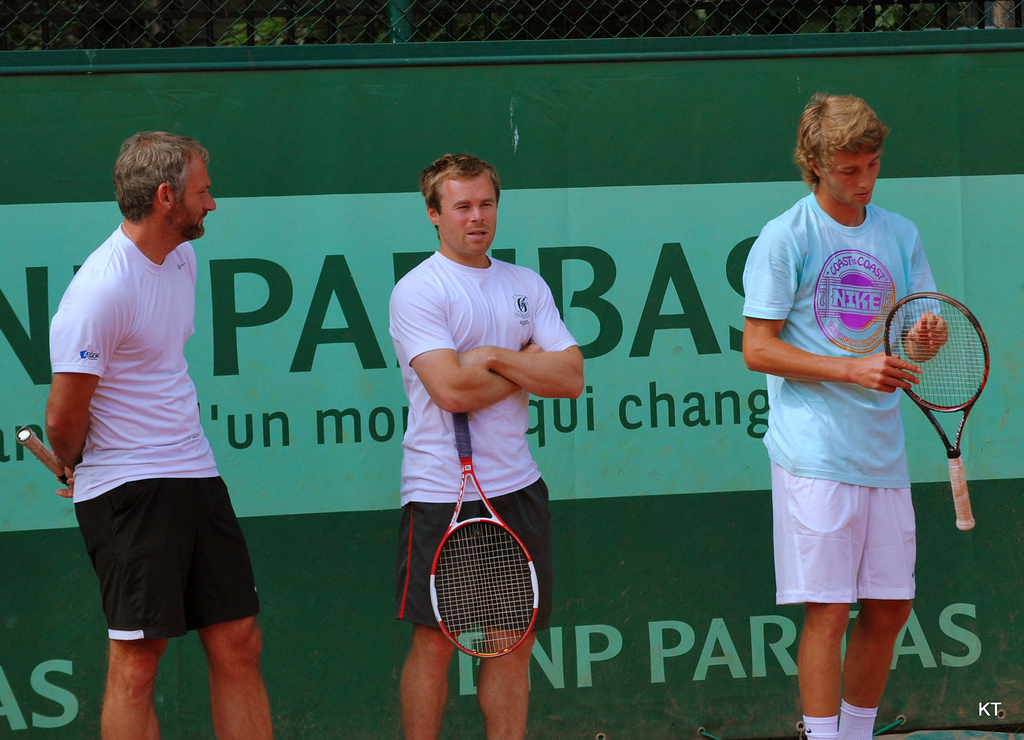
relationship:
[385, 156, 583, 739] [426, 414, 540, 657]
man has a racket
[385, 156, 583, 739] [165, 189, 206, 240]
man has a beard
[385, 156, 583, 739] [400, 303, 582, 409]
man has arms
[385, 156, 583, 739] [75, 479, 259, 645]
man has on shorts